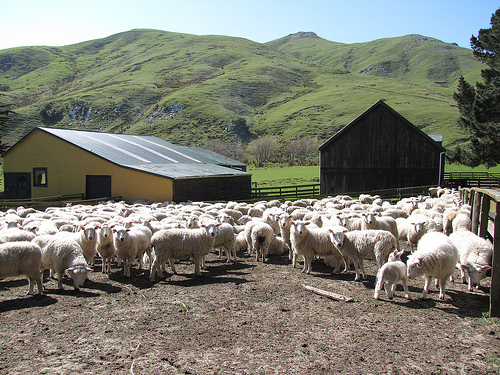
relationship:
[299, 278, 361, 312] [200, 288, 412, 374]
wood on ground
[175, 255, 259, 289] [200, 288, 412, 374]
shadows on ground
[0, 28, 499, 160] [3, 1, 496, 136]
hills are in back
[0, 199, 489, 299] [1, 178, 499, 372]
sheep in pen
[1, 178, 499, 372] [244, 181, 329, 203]
pen has fence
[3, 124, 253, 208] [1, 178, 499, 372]
building near pen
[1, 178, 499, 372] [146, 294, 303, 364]
pen has soil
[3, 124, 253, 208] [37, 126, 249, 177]
building has roof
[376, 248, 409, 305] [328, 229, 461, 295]
lamb between sheep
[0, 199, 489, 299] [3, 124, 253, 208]
sheep near house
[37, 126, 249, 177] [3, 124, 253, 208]
roof on farm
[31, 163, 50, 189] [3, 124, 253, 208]
window on building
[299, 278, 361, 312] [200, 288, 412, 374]
log on ground